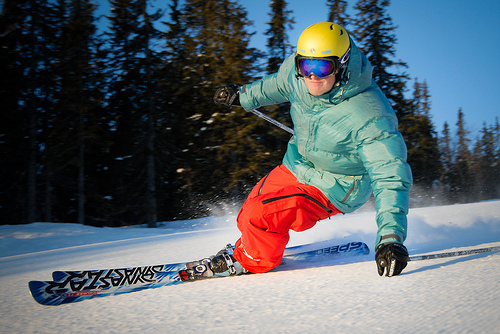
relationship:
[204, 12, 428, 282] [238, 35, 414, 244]
skier wearing blue jacket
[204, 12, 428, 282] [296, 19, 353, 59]
skier wearing helmet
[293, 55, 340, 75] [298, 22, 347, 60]
goggles under helmet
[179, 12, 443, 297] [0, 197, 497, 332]
skier going sideways on snow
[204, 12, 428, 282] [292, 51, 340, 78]
skier wearing goggles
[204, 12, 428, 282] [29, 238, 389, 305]
skier wearing board